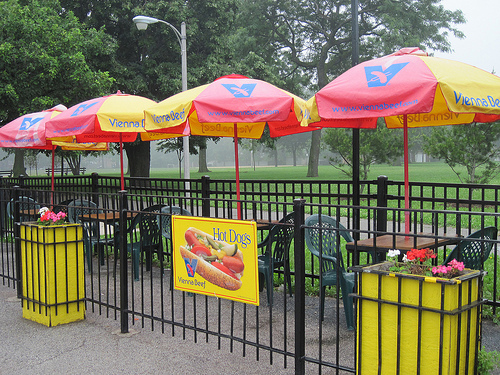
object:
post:
[176, 60, 189, 210]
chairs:
[4, 193, 41, 218]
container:
[345, 269, 482, 362]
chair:
[441, 223, 494, 274]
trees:
[424, 120, 500, 189]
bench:
[34, 156, 85, 175]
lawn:
[407, 161, 445, 183]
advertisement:
[167, 215, 260, 306]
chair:
[306, 215, 364, 333]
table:
[344, 226, 451, 304]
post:
[6, 173, 484, 364]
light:
[131, 7, 203, 218]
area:
[15, 170, 484, 289]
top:
[33, 212, 67, 227]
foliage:
[4, 29, 86, 92]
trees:
[290, 3, 349, 177]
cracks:
[0, 330, 95, 371]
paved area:
[0, 333, 132, 373]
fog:
[206, 141, 227, 170]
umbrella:
[157, 64, 322, 215]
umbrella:
[311, 48, 500, 240]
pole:
[394, 109, 416, 236]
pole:
[229, 119, 249, 222]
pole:
[106, 123, 130, 193]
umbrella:
[42, 88, 177, 190]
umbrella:
[2, 100, 116, 219]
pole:
[45, 145, 55, 196]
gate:
[115, 192, 305, 366]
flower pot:
[350, 258, 483, 304]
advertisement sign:
[169, 214, 264, 307]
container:
[14, 213, 84, 326]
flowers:
[32, 203, 71, 221]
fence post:
[288, 195, 315, 373]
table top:
[82, 205, 150, 229]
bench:
[37, 163, 86, 179]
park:
[3, 6, 471, 214]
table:
[341, 223, 456, 258]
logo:
[177, 254, 197, 282]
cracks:
[85, 311, 109, 333]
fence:
[14, 186, 410, 359]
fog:
[152, 152, 173, 165]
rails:
[250, 194, 346, 372]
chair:
[97, 202, 182, 279]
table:
[71, 198, 151, 265]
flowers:
[381, 241, 479, 281]